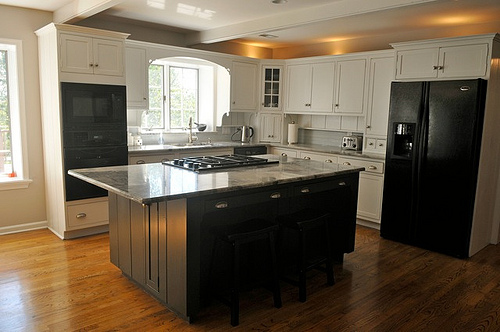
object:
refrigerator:
[379, 77, 498, 260]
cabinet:
[93, 30, 128, 78]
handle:
[75, 214, 87, 218]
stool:
[211, 212, 310, 328]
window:
[168, 64, 198, 130]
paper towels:
[286, 122, 300, 144]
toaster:
[336, 135, 362, 153]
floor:
[0, 219, 500, 330]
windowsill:
[0, 176, 33, 191]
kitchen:
[0, 0, 499, 331]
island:
[66, 153, 368, 328]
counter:
[266, 142, 388, 164]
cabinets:
[331, 53, 368, 116]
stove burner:
[163, 153, 280, 175]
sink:
[169, 142, 212, 147]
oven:
[62, 130, 129, 202]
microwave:
[57, 81, 127, 128]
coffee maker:
[229, 124, 255, 144]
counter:
[125, 139, 267, 157]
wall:
[0, 4, 56, 234]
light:
[236, 38, 289, 60]